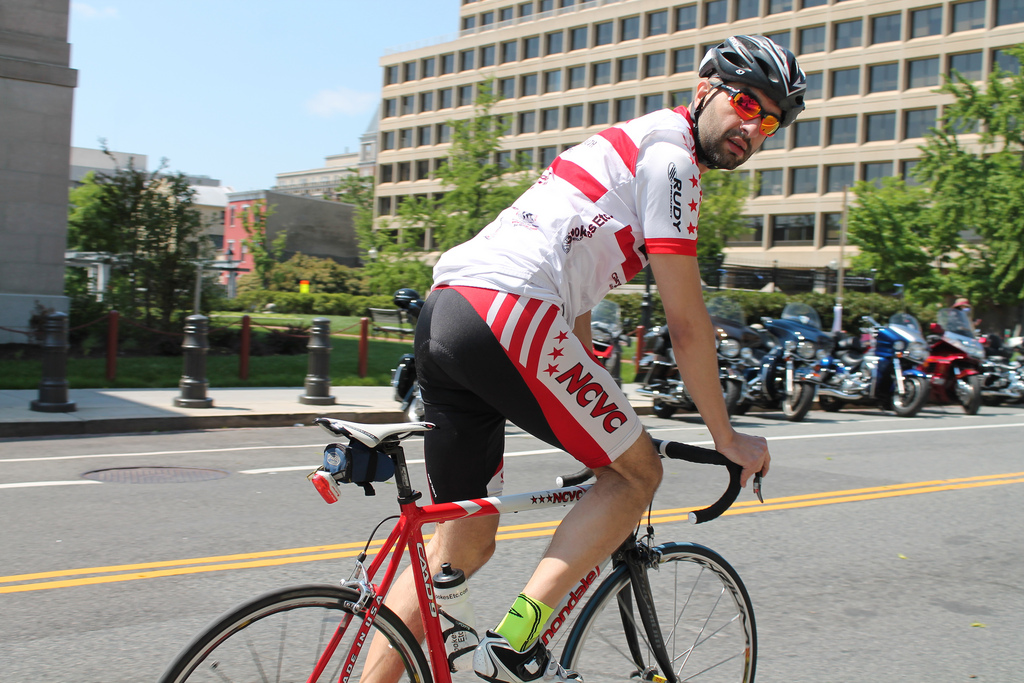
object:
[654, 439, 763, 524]
handle bars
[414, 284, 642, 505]
shorts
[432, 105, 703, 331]
jersey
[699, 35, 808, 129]
helmet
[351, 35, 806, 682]
cyclist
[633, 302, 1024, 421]
bikes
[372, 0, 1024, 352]
building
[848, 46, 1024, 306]
leaves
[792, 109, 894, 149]
window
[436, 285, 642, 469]
stripes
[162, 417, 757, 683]
bike